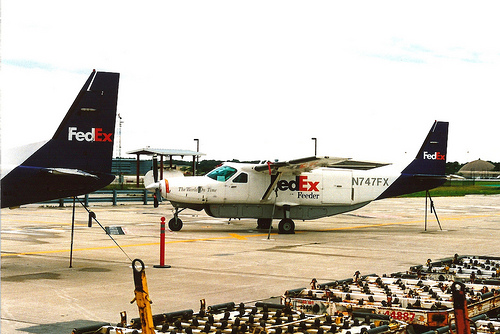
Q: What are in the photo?
A: Planes.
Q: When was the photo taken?
A: Daytime.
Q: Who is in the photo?
A: No one.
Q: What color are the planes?
A: Black and white.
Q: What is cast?
A: Shadow.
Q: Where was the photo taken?
A: Airport.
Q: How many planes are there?
A: Two.